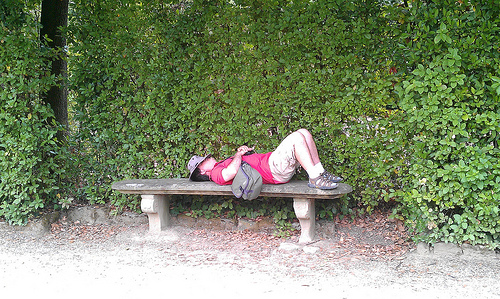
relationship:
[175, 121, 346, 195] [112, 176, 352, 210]
person sleeping on bench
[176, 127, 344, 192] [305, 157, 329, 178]
man wears socks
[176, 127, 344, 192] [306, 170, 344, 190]
man wears sandals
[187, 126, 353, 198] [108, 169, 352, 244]
man laying down on a bench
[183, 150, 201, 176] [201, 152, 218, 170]
hat covering h face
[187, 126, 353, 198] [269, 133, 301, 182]
man wearing shorts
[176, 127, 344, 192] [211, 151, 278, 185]
man wears shirt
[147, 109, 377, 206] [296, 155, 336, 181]
man wears socks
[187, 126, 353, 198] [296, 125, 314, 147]
man has knee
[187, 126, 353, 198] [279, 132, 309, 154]
man has knee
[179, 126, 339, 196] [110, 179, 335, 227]
man on bench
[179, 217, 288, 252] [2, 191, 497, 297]
leaves on ground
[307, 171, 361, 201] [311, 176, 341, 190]
feet in sandals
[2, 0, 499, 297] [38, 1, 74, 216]
garden has entry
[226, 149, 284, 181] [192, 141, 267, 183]
hands on chest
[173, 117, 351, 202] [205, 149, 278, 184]
man wears shirt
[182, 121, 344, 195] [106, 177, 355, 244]
man on bench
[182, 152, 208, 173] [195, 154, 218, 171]
hat on face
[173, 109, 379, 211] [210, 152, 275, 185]
man wears shirt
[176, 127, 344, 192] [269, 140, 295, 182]
man wears shorts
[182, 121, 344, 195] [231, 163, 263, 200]
man holds bag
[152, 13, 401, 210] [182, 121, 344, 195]
bushes behind man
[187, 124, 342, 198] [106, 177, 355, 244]
person on bench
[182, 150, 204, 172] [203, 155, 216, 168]
hat on face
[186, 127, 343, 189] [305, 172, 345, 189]
person wears brown sandals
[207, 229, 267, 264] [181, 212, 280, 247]
leaves under bench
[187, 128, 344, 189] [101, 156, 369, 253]
man on bench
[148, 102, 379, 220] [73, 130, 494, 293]
person on bench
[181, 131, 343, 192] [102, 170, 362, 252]
person on bench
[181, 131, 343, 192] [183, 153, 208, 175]
person wears hat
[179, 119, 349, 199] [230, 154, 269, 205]
person holds bag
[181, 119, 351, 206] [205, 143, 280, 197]
person wears shirt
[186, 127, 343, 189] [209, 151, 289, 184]
person wears shirt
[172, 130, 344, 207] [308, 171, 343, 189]
person wears brown sandals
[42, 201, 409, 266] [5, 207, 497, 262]
leaves on ground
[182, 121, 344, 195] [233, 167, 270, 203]
man holds bag